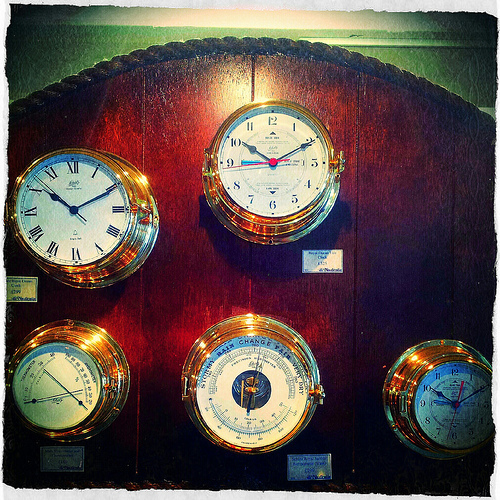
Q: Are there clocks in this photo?
A: Yes, there is a clock.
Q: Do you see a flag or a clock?
A: Yes, there is a clock.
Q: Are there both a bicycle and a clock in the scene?
A: No, there is a clock but no bicycles.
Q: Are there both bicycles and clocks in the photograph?
A: No, there is a clock but no bicycles.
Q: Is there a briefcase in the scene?
A: No, there are no briefcases.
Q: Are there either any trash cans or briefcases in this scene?
A: No, there are no briefcases or trash cans.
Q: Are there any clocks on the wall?
A: Yes, there is a clock on the wall.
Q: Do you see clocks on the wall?
A: Yes, there is a clock on the wall.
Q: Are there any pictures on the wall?
A: No, there is a clock on the wall.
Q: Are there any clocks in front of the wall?
A: Yes, there is a clock in front of the wall.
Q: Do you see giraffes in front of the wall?
A: No, there is a clock in front of the wall.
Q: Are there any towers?
A: No, there are no towers.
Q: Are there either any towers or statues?
A: No, there are no towers or statues.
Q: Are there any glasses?
A: No, there are no glasses.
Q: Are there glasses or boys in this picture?
A: No, there are no glasses or boys.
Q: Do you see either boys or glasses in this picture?
A: No, there are no glasses or boys.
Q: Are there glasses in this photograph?
A: No, there are no glasses.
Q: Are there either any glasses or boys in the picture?
A: No, there are no glasses or boys.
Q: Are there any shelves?
A: No, there are no shelves.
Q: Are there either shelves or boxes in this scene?
A: No, there are no shelves or boxes.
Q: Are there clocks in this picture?
A: Yes, there is a clock.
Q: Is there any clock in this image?
A: Yes, there is a clock.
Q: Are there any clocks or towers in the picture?
A: Yes, there is a clock.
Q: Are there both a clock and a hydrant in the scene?
A: No, there is a clock but no fire hydrants.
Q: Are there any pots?
A: No, there are no pots.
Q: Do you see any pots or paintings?
A: No, there are no pots or paintings.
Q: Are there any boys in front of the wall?
A: No, there is a clock in front of the wall.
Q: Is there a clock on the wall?
A: Yes, there is a clock on the wall.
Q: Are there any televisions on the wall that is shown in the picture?
A: No, there is a clock on the wall.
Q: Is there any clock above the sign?
A: Yes, there is a clock above the sign.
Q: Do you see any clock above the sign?
A: Yes, there is a clock above the sign.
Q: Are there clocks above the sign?
A: Yes, there is a clock above the sign.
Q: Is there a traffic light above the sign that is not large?
A: No, there is a clock above the sign.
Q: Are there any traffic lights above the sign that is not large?
A: No, there is a clock above the sign.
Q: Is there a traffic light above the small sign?
A: No, there is a clock above the sign.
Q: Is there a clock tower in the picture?
A: No, there are no clock towers.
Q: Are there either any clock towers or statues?
A: No, there are no clock towers or statues.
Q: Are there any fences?
A: No, there are no fences.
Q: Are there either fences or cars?
A: No, there are no fences or cars.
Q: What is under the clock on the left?
A: The sign is under the clock.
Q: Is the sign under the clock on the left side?
A: Yes, the sign is under the clock.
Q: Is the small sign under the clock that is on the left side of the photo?
A: Yes, the sign is under the clock.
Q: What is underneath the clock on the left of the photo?
A: The sign is underneath the clock.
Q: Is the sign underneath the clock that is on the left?
A: Yes, the sign is underneath the clock.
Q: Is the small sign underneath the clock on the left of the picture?
A: Yes, the sign is underneath the clock.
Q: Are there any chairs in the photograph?
A: No, there are no chairs.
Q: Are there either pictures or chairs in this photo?
A: No, there are no chairs or pictures.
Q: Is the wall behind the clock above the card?
A: Yes, the wall is behind the clock.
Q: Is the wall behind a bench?
A: No, the wall is behind the clock.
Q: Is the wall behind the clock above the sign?
A: Yes, the wall is behind the clock.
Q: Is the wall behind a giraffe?
A: No, the wall is behind the clock.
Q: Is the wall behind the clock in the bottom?
A: Yes, the wall is behind the clock.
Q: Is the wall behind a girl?
A: No, the wall is behind the clock.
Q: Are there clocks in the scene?
A: Yes, there is a clock.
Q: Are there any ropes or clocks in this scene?
A: Yes, there is a clock.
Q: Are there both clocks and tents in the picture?
A: No, there is a clock but no tents.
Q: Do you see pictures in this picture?
A: No, there are no pictures.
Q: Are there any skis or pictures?
A: No, there are no pictures or skis.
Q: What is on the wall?
A: The clock is on the wall.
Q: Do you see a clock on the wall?
A: Yes, there is a clock on the wall.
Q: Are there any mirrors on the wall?
A: No, there is a clock on the wall.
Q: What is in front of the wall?
A: The clock is in front of the wall.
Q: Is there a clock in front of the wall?
A: Yes, there is a clock in front of the wall.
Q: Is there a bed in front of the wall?
A: No, there is a clock in front of the wall.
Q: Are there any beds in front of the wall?
A: No, there is a clock in front of the wall.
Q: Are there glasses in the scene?
A: No, there are no glasses.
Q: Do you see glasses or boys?
A: No, there are no glasses or boys.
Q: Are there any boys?
A: No, there are no boys.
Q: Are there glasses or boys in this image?
A: No, there are no boys or glasses.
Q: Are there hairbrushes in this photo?
A: No, there are no hairbrushes.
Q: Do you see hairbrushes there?
A: No, there are no hairbrushes.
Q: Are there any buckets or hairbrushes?
A: No, there are no hairbrushes or buckets.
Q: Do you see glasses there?
A: No, there are no glasses.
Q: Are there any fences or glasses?
A: No, there are no glasses or fences.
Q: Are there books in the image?
A: No, there are no books.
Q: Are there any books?
A: No, there are no books.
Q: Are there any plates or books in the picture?
A: No, there are no books or plates.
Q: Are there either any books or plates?
A: No, there are no books or plates.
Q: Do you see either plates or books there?
A: No, there are no books or plates.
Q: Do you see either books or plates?
A: No, there are no books or plates.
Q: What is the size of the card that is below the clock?
A: The card is small.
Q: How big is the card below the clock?
A: The card is small.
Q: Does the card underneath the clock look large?
A: No, the card is small.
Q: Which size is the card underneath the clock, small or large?
A: The card is small.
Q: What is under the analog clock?
A: The card is under the clock.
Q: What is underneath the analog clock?
A: The card is underneath the clock.